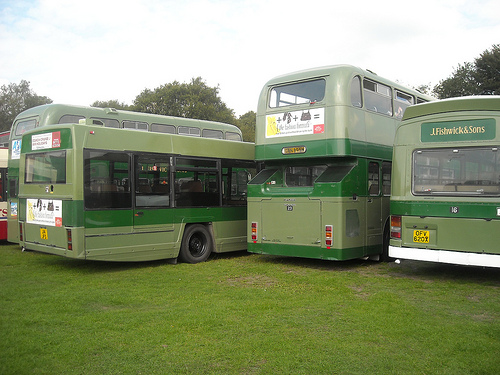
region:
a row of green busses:
[5, 112, 497, 257]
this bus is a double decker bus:
[236, 67, 385, 284]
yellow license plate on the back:
[408, 229, 433, 244]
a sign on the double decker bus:
[249, 108, 341, 145]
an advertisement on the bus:
[18, 190, 67, 228]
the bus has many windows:
[83, 150, 240, 213]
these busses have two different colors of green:
[13, 100, 498, 237]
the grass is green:
[39, 286, 387, 341]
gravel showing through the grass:
[229, 266, 499, 347]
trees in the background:
[64, 56, 285, 126]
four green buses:
[6, 59, 496, 278]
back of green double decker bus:
[242, 54, 387, 271]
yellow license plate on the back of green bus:
[407, 227, 434, 249]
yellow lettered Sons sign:
[466, 123, 488, 135]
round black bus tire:
[174, 218, 220, 273]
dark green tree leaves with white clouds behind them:
[119, 50, 236, 115]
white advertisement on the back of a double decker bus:
[255, 71, 347, 147]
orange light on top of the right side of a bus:
[78, 123, 100, 140]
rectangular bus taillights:
[386, 208, 408, 252]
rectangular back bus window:
[393, 143, 495, 196]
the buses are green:
[11, 51, 498, 288]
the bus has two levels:
[240, 60, 440, 287]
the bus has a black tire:
[155, 205, 232, 272]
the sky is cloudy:
[8, 10, 498, 120]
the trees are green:
[11, 42, 498, 142]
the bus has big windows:
[22, 109, 259, 281]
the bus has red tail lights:
[245, 215, 343, 270]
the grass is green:
[11, 236, 491, 373]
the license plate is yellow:
[386, 197, 466, 273]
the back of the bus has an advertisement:
[257, 104, 332, 149]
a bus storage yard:
[1, 1, 498, 372]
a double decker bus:
[248, 66, 427, 263]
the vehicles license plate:
[410, 228, 431, 244]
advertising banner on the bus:
[264, 109, 323, 134]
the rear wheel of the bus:
[181, 223, 211, 263]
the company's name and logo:
[421, 119, 495, 140]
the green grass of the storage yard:
[1, 245, 498, 374]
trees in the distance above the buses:
[1, 76, 257, 143]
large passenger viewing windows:
[84, 148, 134, 210]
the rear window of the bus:
[411, 146, 499, 198]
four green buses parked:
[16, 85, 472, 294]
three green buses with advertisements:
[11, 91, 364, 328]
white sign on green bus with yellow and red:
[251, 71, 341, 173]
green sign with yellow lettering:
[402, 103, 494, 160]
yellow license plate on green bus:
[388, 214, 450, 270]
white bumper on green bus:
[376, 236, 498, 271]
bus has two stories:
[246, 54, 342, 344]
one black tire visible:
[134, 204, 239, 299]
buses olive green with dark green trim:
[231, 167, 496, 285]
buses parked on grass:
[17, 42, 441, 372]